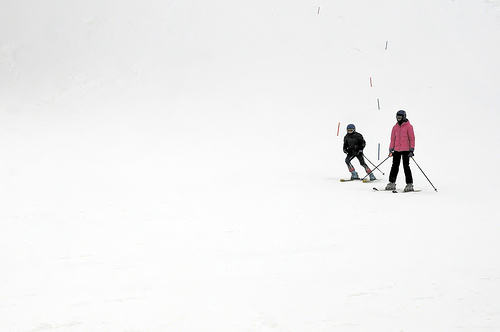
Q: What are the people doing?
A: Skiing.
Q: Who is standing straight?
A: Person in pink.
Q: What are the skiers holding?
A: Poles.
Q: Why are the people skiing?
A: Recreation.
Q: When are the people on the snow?
A: Daytime.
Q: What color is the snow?
A: White.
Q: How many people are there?
A: Two.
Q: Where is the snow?
A: Slope.